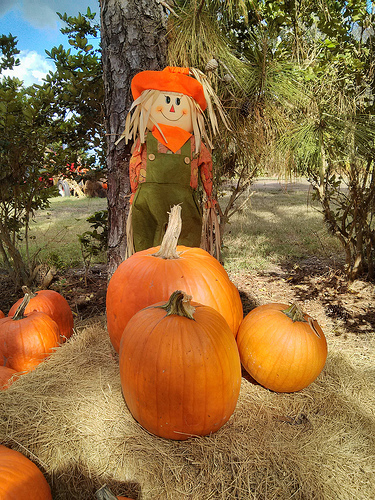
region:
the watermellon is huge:
[129, 298, 264, 438]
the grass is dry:
[203, 447, 362, 480]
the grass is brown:
[196, 449, 359, 489]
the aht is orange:
[125, 71, 221, 96]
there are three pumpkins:
[85, 242, 336, 431]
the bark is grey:
[103, 64, 129, 188]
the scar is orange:
[141, 126, 198, 149]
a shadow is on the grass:
[40, 449, 83, 495]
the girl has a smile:
[124, 93, 201, 211]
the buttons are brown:
[145, 152, 193, 165]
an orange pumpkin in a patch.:
[233, 286, 328, 401]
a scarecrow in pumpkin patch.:
[112, 60, 235, 245]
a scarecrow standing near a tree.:
[108, 38, 252, 267]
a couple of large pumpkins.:
[0, 269, 93, 397]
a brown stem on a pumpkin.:
[142, 194, 191, 263]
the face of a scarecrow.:
[122, 55, 236, 134]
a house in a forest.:
[15, 117, 120, 202]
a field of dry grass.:
[3, 169, 373, 498]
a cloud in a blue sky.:
[0, 44, 80, 99]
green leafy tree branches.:
[43, 4, 99, 91]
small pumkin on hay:
[253, 299, 326, 395]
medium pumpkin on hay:
[102, 293, 260, 440]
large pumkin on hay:
[102, 212, 237, 296]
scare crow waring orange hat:
[127, 52, 240, 241]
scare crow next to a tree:
[142, 56, 215, 241]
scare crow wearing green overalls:
[151, 33, 228, 248]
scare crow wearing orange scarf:
[129, 41, 214, 149]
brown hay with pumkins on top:
[241, 400, 359, 489]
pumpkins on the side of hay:
[12, 281, 68, 355]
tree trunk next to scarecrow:
[103, 0, 164, 64]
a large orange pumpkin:
[115, 291, 246, 442]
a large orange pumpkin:
[96, 202, 246, 362]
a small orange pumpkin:
[238, 295, 330, 399]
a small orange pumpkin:
[5, 282, 77, 343]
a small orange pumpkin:
[1, 295, 63, 370]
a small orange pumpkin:
[0, 443, 59, 498]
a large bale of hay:
[2, 313, 372, 496]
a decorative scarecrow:
[121, 61, 216, 252]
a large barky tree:
[99, 0, 163, 288]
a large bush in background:
[276, 0, 372, 287]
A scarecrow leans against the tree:
[129, 55, 237, 244]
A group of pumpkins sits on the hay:
[20, 257, 358, 438]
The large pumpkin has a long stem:
[100, 195, 251, 323]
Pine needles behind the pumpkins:
[210, 27, 338, 198]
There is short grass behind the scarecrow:
[269, 189, 303, 227]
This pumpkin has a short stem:
[282, 298, 330, 353]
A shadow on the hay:
[46, 450, 97, 492]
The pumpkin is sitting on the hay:
[110, 300, 256, 485]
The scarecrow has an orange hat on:
[115, 56, 215, 97]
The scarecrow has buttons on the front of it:
[137, 130, 203, 195]